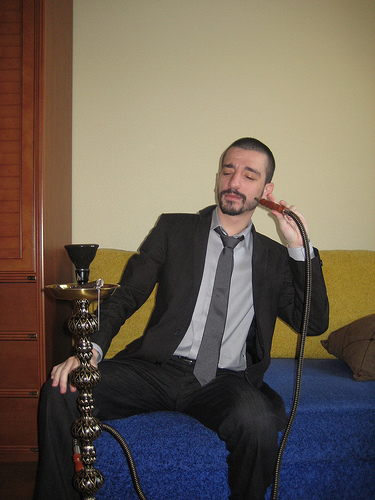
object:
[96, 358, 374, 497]
bedspread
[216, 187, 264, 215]
beard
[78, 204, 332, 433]
jacket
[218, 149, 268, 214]
face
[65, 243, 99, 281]
top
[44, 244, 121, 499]
bong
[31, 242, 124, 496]
bowl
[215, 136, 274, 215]
head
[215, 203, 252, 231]
neck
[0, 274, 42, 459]
dresser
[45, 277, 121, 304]
gold trimming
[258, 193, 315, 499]
tube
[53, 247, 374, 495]
bed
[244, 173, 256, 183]
eye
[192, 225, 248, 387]
tie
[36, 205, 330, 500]
black suit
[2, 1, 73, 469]
cabinet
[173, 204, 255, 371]
shirt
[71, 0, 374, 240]
wall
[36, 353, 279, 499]
pants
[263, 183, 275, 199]
ear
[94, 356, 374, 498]
covering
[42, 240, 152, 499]
hookah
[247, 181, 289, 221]
hookah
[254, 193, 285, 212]
nozzle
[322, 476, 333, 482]
spot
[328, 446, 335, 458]
spot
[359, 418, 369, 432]
spot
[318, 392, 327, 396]
spot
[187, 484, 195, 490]
spot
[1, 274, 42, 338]
drawer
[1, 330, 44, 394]
drawer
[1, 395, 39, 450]
drawer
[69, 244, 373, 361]
pillow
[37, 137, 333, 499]
man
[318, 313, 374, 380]
pillow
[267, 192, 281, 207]
finger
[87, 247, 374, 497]
sofa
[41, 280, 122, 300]
ashtray